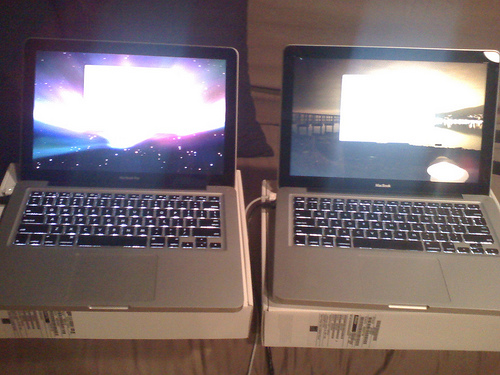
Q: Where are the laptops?
A: On boxes.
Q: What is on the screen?
A: Bright light.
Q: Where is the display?
A: On the laptop.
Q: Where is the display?
A: On the laptop.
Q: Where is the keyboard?
A: On the laptop.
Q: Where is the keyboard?
A: On the laptop.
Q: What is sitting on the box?
A: A computer.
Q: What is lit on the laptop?
A: Screen and keys.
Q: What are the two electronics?
A: Computers.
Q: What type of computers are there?
A: Laptop.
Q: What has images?
A: Two computer screens.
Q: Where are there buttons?
A: Keyboard.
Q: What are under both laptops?
A: Boxes.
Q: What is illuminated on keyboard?
A: Buttons.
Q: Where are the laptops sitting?
A: Side by side.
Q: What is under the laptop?
A: A white box.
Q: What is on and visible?
A: Computer Monitor.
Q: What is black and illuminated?
A: Keyboard.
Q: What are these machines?
A: Laptops.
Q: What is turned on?
A: Two laptop computers.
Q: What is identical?
A: Two computers.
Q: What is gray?
A: The computers.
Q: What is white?
A: The computer plug.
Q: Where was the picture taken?
A: In an office.